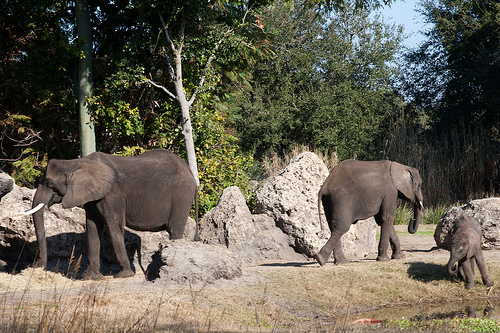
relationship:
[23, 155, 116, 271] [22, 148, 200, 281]
head of elephant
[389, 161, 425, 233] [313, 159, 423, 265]
head of elephant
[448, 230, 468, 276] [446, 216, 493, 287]
head of elephant